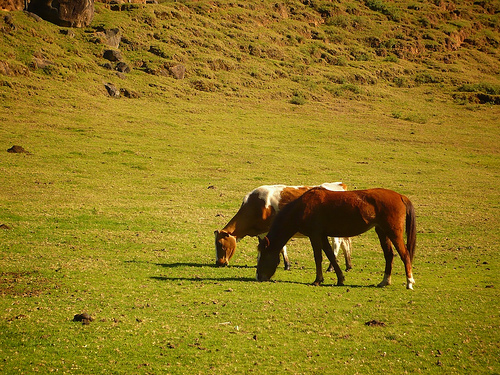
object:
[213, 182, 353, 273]
animals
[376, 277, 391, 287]
hoof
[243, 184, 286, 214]
white spot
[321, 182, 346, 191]
white spot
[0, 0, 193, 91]
hill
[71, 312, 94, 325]
dirt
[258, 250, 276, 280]
face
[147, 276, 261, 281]
shadow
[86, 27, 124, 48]
couch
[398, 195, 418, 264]
tail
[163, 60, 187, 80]
rock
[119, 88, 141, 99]
boulders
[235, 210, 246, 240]
neck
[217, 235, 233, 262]
face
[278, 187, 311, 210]
spot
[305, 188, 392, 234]
side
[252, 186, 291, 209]
side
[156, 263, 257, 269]
shadow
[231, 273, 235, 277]
grass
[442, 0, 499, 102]
hillside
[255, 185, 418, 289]
animals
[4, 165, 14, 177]
grass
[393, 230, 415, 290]
leg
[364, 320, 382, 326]
rock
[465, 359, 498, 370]
grass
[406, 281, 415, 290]
foot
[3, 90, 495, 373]
field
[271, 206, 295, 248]
neck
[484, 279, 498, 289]
grass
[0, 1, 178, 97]
outcropping